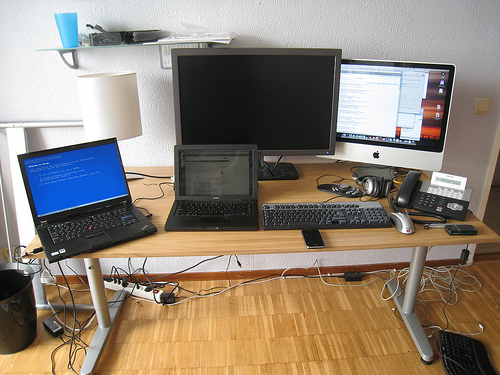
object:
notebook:
[162, 144, 259, 233]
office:
[2, 0, 498, 373]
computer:
[316, 54, 456, 183]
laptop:
[17, 137, 158, 265]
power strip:
[102, 275, 165, 304]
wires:
[167, 258, 402, 306]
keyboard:
[434, 327, 497, 374]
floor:
[3, 259, 498, 375]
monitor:
[168, 47, 342, 182]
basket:
[1, 268, 37, 357]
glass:
[52, 11, 81, 47]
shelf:
[29, 36, 234, 71]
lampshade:
[76, 72, 144, 143]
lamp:
[76, 70, 147, 183]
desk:
[17, 160, 500, 374]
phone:
[394, 169, 475, 223]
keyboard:
[260, 201, 394, 231]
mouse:
[388, 209, 416, 235]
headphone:
[354, 174, 394, 201]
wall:
[1, 0, 499, 285]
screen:
[15, 141, 131, 218]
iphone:
[299, 229, 325, 250]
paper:
[156, 35, 234, 45]